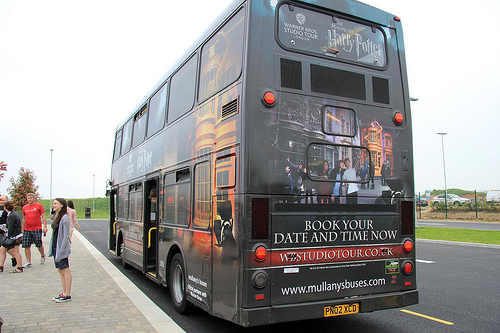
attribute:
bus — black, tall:
[106, 1, 419, 328]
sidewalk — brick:
[1, 224, 185, 331]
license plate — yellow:
[324, 303, 364, 315]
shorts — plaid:
[23, 230, 45, 249]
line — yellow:
[402, 308, 455, 327]